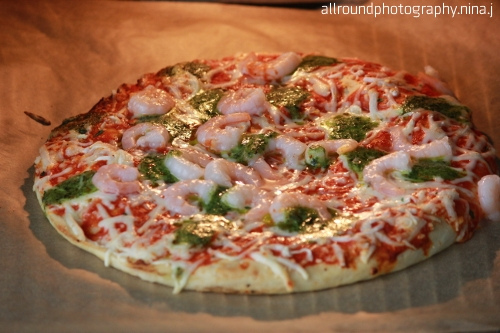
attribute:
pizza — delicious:
[42, 57, 487, 313]